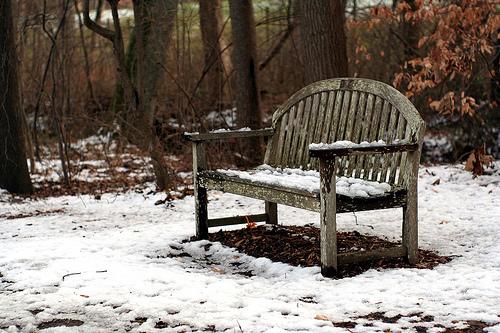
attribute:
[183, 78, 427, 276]
bench — old, covered, empty, wooden, aged, classic, sturdy, brown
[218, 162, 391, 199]
snow — white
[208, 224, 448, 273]
leaves — brown, dry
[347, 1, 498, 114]
leaves — brown, dead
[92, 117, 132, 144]
branch — bare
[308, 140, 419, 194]
arm — wooden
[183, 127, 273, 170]
arm — wooden